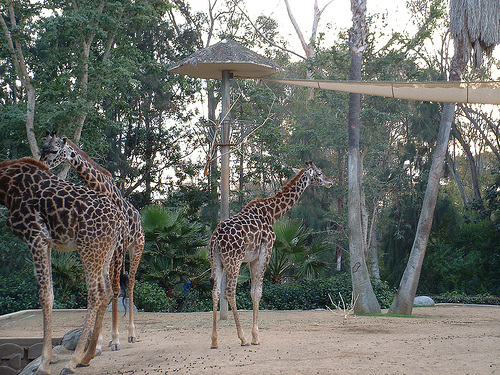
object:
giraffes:
[0, 155, 130, 374]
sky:
[0, 1, 499, 203]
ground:
[0, 302, 498, 375]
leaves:
[80, 60, 90, 68]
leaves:
[193, 99, 198, 103]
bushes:
[0, 202, 398, 312]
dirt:
[0, 306, 499, 374]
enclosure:
[0, 120, 498, 374]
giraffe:
[205, 160, 336, 351]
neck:
[250, 167, 308, 223]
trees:
[383, 3, 467, 318]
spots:
[50, 194, 64, 212]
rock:
[412, 294, 433, 308]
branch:
[203, 21, 216, 49]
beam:
[213, 69, 235, 319]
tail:
[114, 210, 133, 321]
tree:
[335, 0, 380, 319]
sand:
[0, 307, 498, 375]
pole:
[212, 68, 244, 322]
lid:
[168, 35, 283, 78]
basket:
[193, 111, 255, 225]